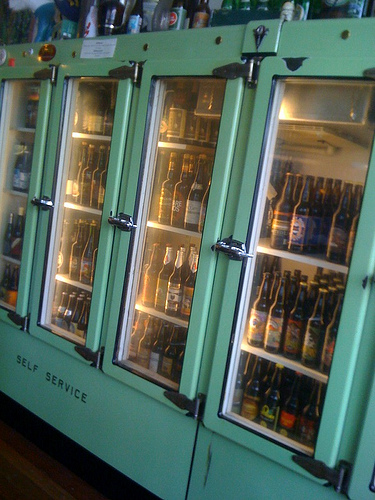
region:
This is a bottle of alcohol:
[298, 374, 329, 458]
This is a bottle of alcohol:
[280, 361, 305, 443]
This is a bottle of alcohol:
[259, 358, 285, 444]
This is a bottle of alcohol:
[240, 351, 265, 433]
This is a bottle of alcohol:
[319, 288, 350, 372]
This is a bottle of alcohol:
[304, 282, 330, 368]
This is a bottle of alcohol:
[267, 269, 288, 354]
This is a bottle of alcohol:
[251, 268, 272, 351]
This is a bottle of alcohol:
[325, 182, 352, 278]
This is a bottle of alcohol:
[288, 171, 319, 274]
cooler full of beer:
[11, 32, 365, 495]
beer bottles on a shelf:
[272, 173, 358, 259]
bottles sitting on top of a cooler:
[11, 1, 362, 46]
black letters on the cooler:
[12, 346, 83, 409]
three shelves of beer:
[251, 147, 358, 465]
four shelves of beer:
[129, 74, 221, 379]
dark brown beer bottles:
[257, 273, 329, 363]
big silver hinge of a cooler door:
[210, 234, 247, 267]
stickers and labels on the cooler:
[5, 40, 129, 72]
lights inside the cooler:
[64, 82, 115, 200]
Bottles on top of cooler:
[6, 1, 371, 41]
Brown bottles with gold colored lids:
[284, 271, 344, 368]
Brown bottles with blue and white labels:
[287, 164, 342, 253]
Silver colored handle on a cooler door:
[204, 230, 263, 269]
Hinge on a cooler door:
[160, 383, 212, 427]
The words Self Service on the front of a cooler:
[11, 352, 93, 409]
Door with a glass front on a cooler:
[27, 52, 138, 377]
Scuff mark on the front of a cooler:
[195, 431, 218, 489]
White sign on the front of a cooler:
[75, 32, 121, 57]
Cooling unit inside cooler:
[186, 78, 373, 156]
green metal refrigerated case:
[3, 19, 373, 499]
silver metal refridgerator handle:
[214, 236, 248, 260]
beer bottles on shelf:
[246, 268, 334, 369]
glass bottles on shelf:
[156, 151, 212, 235]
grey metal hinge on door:
[245, 60, 259, 85]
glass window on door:
[119, 73, 217, 377]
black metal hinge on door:
[164, 389, 203, 419]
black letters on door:
[15, 355, 91, 404]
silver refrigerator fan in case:
[195, 83, 373, 153]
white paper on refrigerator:
[80, 41, 118, 59]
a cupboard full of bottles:
[5, 53, 366, 488]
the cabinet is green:
[1, 17, 372, 499]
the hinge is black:
[287, 445, 350, 498]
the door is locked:
[211, 237, 260, 269]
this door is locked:
[105, 214, 138, 234]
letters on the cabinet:
[12, 353, 91, 407]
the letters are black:
[15, 350, 90, 411]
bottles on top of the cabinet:
[4, 0, 373, 48]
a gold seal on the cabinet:
[34, 44, 58, 61]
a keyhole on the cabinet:
[249, 24, 268, 49]